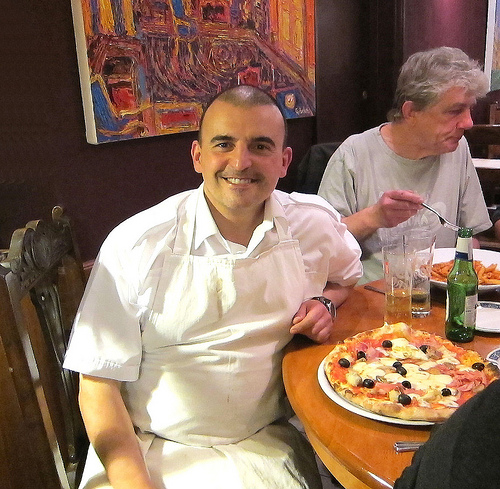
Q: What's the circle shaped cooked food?
A: Pizza.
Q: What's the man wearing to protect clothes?
A: Apron.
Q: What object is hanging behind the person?
A: Painting.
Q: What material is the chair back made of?
A: Wood.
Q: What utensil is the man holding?
A: Fork.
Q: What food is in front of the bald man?
A: Pizza.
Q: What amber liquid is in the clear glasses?
A: Beer.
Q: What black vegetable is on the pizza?
A: Black olives.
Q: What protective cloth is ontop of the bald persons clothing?
A: Apron.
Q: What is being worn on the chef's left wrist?
A: A watch.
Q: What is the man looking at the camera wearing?
A: A white apron.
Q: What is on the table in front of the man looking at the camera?
A: A pizza.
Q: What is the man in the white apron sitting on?
A: A wooden chair.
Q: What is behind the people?
A: A painting.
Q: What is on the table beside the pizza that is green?
A: A beer bottle.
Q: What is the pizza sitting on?
A: A white plate.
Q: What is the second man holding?
A: A fork.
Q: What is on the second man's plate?
A: Pasta.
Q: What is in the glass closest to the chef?
A: Beer.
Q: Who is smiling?
A: The cook.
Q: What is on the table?
A: A pizza.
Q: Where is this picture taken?
A: A restaurant.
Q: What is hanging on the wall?
A: A painting.